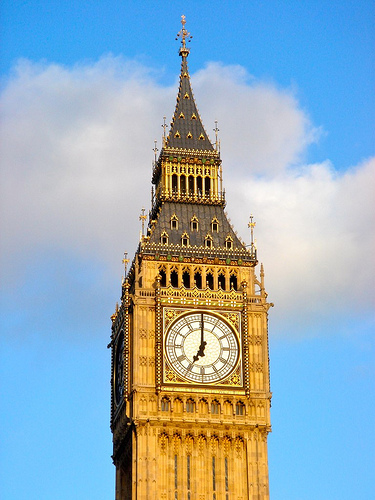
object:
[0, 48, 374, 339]
cloud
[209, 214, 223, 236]
window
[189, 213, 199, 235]
window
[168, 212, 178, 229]
window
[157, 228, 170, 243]
window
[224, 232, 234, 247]
window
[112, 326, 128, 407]
clock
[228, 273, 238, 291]
doorway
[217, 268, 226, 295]
doorway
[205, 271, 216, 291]
doorway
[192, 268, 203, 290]
doorway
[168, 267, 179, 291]
doorway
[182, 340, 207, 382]
hand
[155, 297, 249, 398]
clock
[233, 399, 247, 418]
arch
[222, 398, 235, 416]
arch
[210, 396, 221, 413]
arch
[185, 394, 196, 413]
arch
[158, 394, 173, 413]
arch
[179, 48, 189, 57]
ball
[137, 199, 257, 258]
roof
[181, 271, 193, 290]
gate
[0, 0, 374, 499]
blue sky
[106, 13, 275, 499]
building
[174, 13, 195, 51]
cross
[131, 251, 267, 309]
cornice design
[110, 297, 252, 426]
two clock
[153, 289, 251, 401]
elegant frame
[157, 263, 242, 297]
seven doorways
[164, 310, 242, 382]
clock face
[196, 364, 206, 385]
roman numerals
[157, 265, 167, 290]
open arches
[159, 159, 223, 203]
parapets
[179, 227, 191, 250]
windows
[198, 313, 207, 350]
black hands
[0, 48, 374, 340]
puffy clouds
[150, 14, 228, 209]
pointed roof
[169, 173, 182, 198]
arched openings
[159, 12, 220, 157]
spire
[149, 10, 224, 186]
decoration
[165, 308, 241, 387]
time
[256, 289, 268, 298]
green decorations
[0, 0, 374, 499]
it is sunny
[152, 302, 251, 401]
clock gate